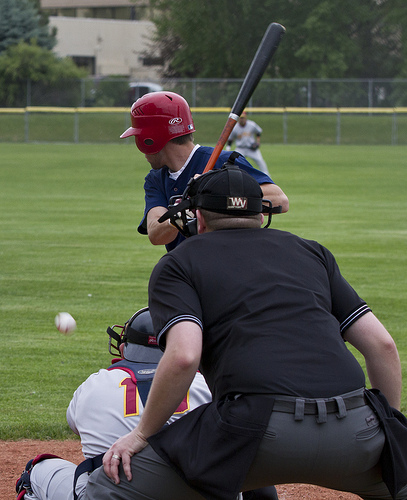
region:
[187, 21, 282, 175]
a red and black baseball bat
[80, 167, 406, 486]
a baseball umpire watching play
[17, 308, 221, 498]
a squating baseball catcher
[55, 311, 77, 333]
a white baseball with red stitching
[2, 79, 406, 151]
a grey metal fence in the outfield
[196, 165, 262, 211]
a black ball cap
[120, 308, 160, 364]
a dark blue hard protective helmet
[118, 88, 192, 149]
a red protective helmet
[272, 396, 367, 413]
a black leather belt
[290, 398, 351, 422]
three close belt loops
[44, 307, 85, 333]
blurry white and red baseball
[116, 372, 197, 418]
red number on jersey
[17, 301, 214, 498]
man wearing umpire uniform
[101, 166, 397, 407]
man wearing black shirt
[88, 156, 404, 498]
man wearing grey pants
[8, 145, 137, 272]
green grassy baseball field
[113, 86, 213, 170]
man wearing red baseball helmet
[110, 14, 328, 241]
man holding baseball bat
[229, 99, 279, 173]
baseball player standing in field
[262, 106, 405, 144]
fence around baseball field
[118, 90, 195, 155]
Red baseball helmet on player's head.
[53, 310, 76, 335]
Baseball in the air.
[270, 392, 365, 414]
Black belt around man's waist.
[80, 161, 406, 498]
Man umpiring baseball game.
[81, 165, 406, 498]
Man wearing black shirt.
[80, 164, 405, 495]
Man wearing grey pants.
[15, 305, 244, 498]
Man playing baseball.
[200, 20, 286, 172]
Black baseball bat.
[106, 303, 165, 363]
Black catcher's helmet.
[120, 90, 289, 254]
Baseball player wearing a uniform.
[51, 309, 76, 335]
A baseball is in the air.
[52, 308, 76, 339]
The colors of a baseball are white and red.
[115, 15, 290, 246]
A baseball player is holding a bat.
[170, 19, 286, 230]
The colors of a baseball bat are black, white, and orange.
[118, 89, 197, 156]
A batter is wearing a red helmet.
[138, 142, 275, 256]
A batter is wearing a blue and white top.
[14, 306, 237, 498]
A catcher is crouching down.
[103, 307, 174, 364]
A catcher is wearing a protective helmet.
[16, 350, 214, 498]
A catcher is wearing a white, black, and red uniform.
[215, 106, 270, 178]
A baseball player is in the background.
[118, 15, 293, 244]
Baseball player holding a bat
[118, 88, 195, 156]
Baseball player wearing red helmet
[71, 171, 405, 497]
Umpire watching the baseball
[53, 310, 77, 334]
Baseball flying toward catcher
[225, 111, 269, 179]
Baseball player standing in outfield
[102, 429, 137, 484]
Ring on umpire's finger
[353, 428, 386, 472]
Umpire has wallet in back pocket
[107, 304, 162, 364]
Catcher wearing black helmet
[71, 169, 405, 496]
Umpire wearing black shirt is bending over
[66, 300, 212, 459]
Catcher is wearing gray and red jersey